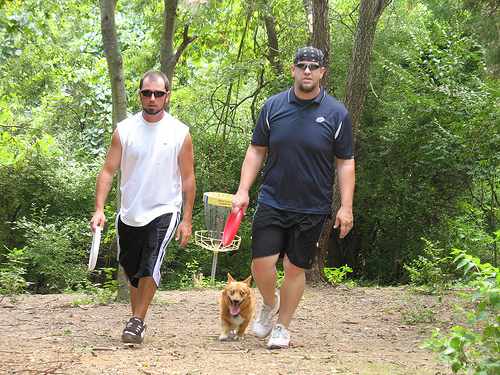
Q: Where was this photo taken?
A: In the woods.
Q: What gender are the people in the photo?
A: Male.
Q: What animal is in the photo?
A: A dog.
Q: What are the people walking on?
A: Gravel.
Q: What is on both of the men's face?
A: Sunglasses.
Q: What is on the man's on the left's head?
A: A bandana.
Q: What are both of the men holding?
A: Frisbees.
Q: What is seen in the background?
A: Trees.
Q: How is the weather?
A: Sunny.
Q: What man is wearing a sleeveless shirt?
A: The man on the left.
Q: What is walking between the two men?
A: A dog.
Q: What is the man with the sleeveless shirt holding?
A: A frisbee.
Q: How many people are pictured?
A: Two.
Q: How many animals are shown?
A: One.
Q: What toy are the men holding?
A: Frisbees.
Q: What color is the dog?
A: Brown.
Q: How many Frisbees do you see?
A: Two.